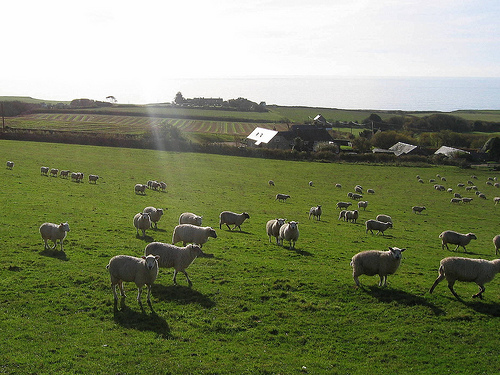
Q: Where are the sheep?
A: In a green pasture.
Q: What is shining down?
A: A ray of sunlight.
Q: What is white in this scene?
A: The sheep.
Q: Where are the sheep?
A: In a field covered with green grass.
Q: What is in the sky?
A: Clouds.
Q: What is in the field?
A: Sheep.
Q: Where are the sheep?
A: Field.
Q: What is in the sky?
A: Cloud.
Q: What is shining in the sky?
A: Sun.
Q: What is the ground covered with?
A: Green grass.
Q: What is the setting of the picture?
A: Farmland.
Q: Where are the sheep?
A: In a field.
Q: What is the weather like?
A: Mostly clear.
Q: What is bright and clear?
A: The sky.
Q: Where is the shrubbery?
A: On the border of the field.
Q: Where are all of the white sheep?
A: In the field.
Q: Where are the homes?
A: In the field.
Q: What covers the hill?
A: Green grass.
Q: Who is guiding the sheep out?
A: No one.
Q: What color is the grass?
A: Green.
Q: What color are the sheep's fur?
A: White.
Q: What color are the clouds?
A: White.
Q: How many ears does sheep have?
A: Two.